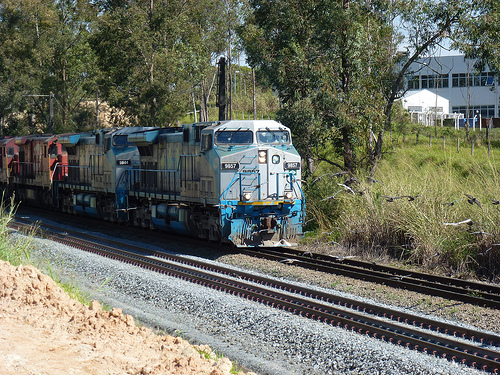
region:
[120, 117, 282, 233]
this is a train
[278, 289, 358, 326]
this is the railway line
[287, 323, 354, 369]
these are small rocks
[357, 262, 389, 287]
this is a metal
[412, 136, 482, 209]
this is a grass area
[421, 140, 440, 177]
the grass is green in color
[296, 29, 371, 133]
this is a tree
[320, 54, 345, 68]
the leaves are green in color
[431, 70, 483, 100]
this is a building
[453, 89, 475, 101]
the wall is white in color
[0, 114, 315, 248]
a long blue and red train.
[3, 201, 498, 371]
train tracks under a train.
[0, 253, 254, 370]
a section of red rock.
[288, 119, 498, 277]
a field filled with green grass.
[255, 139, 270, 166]
A headlight on a train.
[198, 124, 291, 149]
wind shields on a train.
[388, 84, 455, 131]
a white building near a field.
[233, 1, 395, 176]
a tree filled with leaves.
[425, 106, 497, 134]
a parking lot near a building.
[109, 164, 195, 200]
a railing on a train.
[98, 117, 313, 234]
long blue train car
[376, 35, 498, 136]
white building and fence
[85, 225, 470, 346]
long metal train tracks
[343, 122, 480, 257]
tall grass in field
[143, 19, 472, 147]
many full green trees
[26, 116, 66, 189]
red train car behind blue train car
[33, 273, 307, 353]
many types of rocks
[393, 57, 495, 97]
clear windows on white building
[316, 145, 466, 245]
many birds in grass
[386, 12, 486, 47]
blue sky with clouds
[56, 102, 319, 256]
light blue engine on train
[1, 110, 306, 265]
train going down train tracks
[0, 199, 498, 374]
elevated section of gravel under train tracks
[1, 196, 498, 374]
metal train tracks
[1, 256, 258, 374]
light brown dirt hillside next to train tracks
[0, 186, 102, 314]
green grass on hillside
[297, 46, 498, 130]
white building near train tracks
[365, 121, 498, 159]
wooden fence posts stretching across grassy field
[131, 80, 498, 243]
large grassy field next to train tracks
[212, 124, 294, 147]
wide clear train windows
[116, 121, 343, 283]
A train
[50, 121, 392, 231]
An engine on the tracks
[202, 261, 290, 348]
train tracks on the stones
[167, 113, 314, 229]
Blue train with lights on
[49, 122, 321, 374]
A train pulling train cars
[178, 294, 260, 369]
limestone under the tracks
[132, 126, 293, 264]
diesel engine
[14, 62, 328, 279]
moving product by train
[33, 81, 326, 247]
The train on the tracks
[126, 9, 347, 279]
Going to the train yard to load